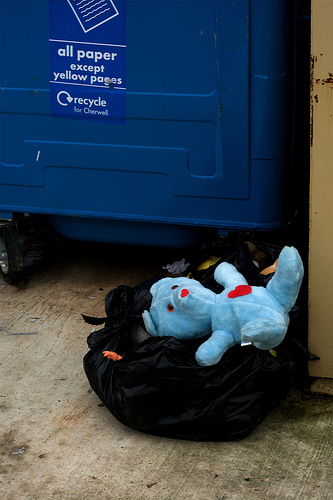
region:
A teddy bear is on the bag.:
[143, 244, 303, 364]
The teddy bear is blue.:
[218, 304, 276, 332]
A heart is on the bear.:
[226, 284, 250, 297]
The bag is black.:
[132, 384, 235, 417]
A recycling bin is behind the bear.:
[141, 69, 269, 192]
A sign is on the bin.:
[48, 0, 126, 122]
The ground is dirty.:
[0, 426, 48, 475]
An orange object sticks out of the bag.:
[102, 350, 121, 360]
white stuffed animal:
[132, 242, 308, 370]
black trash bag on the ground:
[67, 221, 332, 455]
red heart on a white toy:
[223, 281, 258, 302]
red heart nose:
[180, 287, 189, 299]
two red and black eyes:
[163, 280, 180, 315]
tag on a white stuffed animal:
[238, 335, 254, 348]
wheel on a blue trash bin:
[1, 219, 29, 289]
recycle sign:
[53, 88, 73, 109]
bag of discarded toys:
[76, 224, 318, 453]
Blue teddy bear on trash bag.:
[135, 241, 308, 368]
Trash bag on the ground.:
[78, 262, 319, 445]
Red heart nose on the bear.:
[177, 283, 189, 301]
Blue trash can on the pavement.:
[0, 0, 297, 284]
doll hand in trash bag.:
[98, 348, 125, 365]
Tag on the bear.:
[236, 332, 254, 349]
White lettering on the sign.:
[41, 27, 120, 120]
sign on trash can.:
[41, 1, 132, 126]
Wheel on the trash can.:
[0, 215, 40, 297]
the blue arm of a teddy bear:
[195, 328, 234, 364]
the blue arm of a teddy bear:
[213, 260, 241, 286]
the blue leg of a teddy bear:
[240, 318, 283, 346]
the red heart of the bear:
[181, 287, 189, 298]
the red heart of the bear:
[227, 282, 252, 297]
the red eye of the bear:
[167, 302, 174, 311]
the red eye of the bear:
[171, 283, 178, 289]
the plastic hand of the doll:
[101, 349, 120, 361]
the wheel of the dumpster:
[1, 224, 27, 284]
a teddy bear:
[145, 244, 294, 361]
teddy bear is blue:
[139, 244, 298, 366]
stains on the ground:
[2, 427, 33, 463]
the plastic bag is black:
[165, 388, 236, 421]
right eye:
[164, 302, 178, 310]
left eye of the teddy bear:
[168, 281, 180, 290]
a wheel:
[6, 233, 32, 278]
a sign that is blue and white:
[48, 36, 136, 120]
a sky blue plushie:
[141, 244, 302, 366]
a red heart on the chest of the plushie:
[228, 285, 251, 297]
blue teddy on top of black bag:
[140, 239, 306, 376]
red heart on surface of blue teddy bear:
[223, 279, 251, 299]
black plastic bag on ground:
[75, 234, 321, 441]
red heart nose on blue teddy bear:
[177, 285, 189, 298]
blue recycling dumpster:
[0, 0, 305, 285]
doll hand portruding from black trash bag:
[98, 346, 120, 361]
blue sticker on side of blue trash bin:
[42, 0, 129, 127]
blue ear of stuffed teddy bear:
[139, 309, 161, 339]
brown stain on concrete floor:
[1, 418, 55, 478]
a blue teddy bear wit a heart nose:
[140, 244, 304, 366]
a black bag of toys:
[80, 285, 296, 439]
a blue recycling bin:
[0, 0, 307, 282]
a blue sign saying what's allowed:
[47, 0, 129, 126]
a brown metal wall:
[306, 0, 331, 378]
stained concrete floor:
[0, 252, 330, 499]